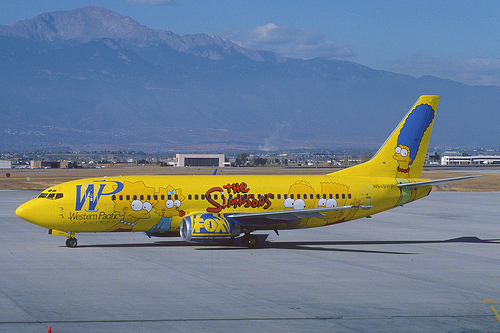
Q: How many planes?
A: One.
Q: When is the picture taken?
A: Daytime.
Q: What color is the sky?
A: Blue.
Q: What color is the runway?
A: Gray.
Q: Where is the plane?
A: Runway.